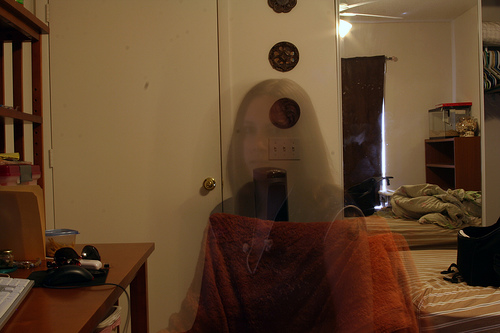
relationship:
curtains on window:
[337, 55, 412, 220] [376, 99, 390, 189]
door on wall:
[49, 3, 221, 326] [1, 0, 346, 332]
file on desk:
[3, 184, 50, 270] [1, 2, 158, 332]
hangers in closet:
[483, 48, 498, 90] [481, 1, 498, 229]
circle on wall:
[268, 97, 301, 127] [222, 0, 336, 215]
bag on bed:
[439, 217, 498, 290] [386, 247, 498, 331]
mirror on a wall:
[216, 1, 498, 240] [0, 1, 498, 331]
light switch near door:
[266, 133, 311, 173] [49, 3, 221, 326]